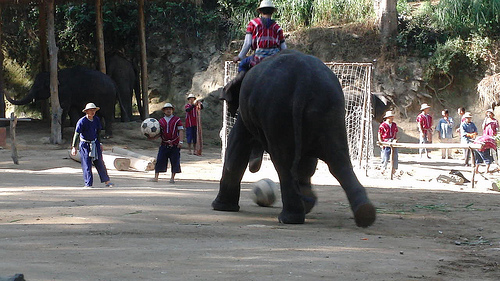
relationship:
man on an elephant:
[236, 0, 288, 58] [212, 53, 375, 227]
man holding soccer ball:
[160, 102, 186, 183] [139, 116, 161, 140]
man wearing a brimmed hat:
[71, 101, 114, 195] [82, 101, 101, 114]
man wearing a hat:
[71, 101, 114, 195] [82, 101, 101, 114]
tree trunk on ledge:
[375, 1, 400, 55] [296, 1, 499, 52]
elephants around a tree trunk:
[27, 66, 81, 120] [46, 1, 66, 148]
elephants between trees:
[27, 66, 81, 120] [0, 1, 151, 104]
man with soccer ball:
[160, 102, 186, 183] [139, 116, 161, 140]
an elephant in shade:
[27, 66, 81, 120] [1, 70, 73, 143]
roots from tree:
[372, 1, 453, 104] [375, 1, 400, 55]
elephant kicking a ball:
[212, 53, 375, 227] [251, 176, 279, 212]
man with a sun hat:
[236, 0, 288, 58] [257, 0, 280, 12]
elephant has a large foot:
[212, 53, 375, 227] [211, 195, 242, 215]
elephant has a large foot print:
[212, 53, 375, 227] [211, 195, 242, 215]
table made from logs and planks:
[379, 138, 492, 187] [380, 138, 499, 199]